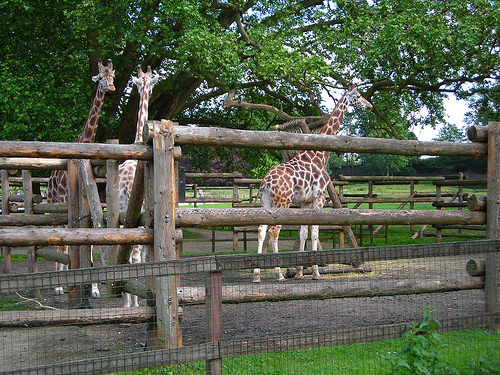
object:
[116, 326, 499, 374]
lawn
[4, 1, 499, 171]
tree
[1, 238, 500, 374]
net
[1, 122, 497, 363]
fence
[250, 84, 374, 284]
giraffe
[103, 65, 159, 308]
giraffe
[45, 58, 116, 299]
giraffe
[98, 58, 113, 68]
antlers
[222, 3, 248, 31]
branch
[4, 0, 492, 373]
zoo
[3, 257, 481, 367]
dirt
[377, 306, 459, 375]
bush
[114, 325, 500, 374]
grass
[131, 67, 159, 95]
head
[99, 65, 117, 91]
head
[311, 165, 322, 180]
spot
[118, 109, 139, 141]
trunk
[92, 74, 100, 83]
ear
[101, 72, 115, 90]
face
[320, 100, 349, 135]
neck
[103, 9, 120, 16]
leaf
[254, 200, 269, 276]
leg